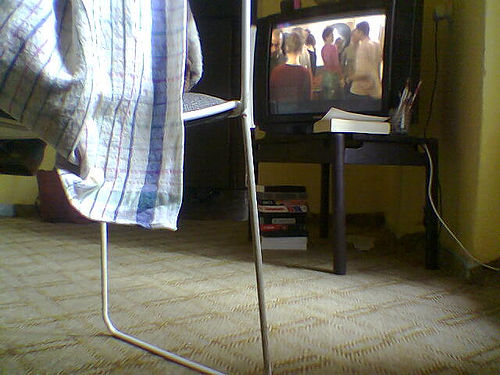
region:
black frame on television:
[238, 0, 415, 146]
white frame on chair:
[77, 1, 302, 356]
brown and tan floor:
[157, 242, 436, 342]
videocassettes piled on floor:
[250, 181, 311, 245]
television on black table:
[242, 134, 429, 275]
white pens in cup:
[392, 82, 426, 138]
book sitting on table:
[310, 107, 379, 142]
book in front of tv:
[295, 117, 387, 138]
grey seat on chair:
[183, 48, 251, 143]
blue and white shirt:
[30, 5, 175, 228]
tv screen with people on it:
[262, 15, 391, 119]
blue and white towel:
[0, 0, 200, 237]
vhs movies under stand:
[256, 178, 309, 255]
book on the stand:
[304, 101, 393, 139]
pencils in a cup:
[392, 74, 428, 139]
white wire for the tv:
[417, 135, 492, 282]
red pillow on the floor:
[24, 162, 64, 232]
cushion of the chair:
[184, 91, 232, 115]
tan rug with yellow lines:
[302, 301, 381, 358]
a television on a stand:
[59, 6, 438, 276]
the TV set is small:
[250, 8, 435, 136]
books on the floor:
[239, 171, 321, 254]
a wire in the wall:
[413, 5, 498, 280]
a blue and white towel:
[25, 13, 199, 238]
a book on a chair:
[312, 101, 400, 144]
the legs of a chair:
[79, 88, 292, 371]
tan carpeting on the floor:
[34, 248, 448, 355]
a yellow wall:
[431, 21, 494, 264]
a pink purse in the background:
[25, 165, 100, 225]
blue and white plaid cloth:
[17, 35, 196, 261]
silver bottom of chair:
[130, 250, 289, 314]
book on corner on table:
[307, 90, 396, 155]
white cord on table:
[423, 154, 491, 259]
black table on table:
[233, 8, 424, 122]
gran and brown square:
[327, 300, 404, 367]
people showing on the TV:
[289, 57, 377, 143]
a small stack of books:
[261, 169, 323, 285]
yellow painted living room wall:
[458, 46, 495, 111]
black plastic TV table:
[276, 129, 351, 202]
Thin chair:
[99, 4, 269, 374]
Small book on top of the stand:
[312, 103, 393, 134]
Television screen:
[242, 2, 420, 134]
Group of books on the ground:
[245, 178, 313, 260]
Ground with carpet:
[5, 213, 495, 371]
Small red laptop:
[34, 168, 88, 226]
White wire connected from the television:
[417, 136, 498, 276]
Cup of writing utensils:
[388, 76, 422, 131]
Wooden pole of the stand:
[328, 133, 349, 277]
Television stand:
[248, 133, 442, 275]